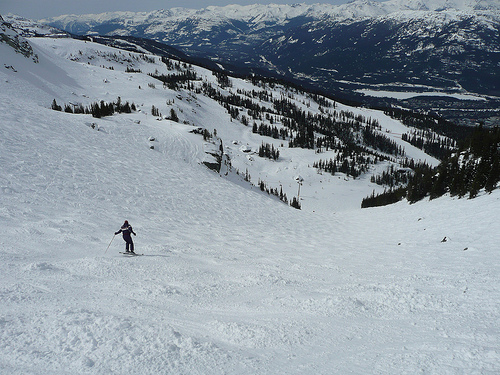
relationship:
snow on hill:
[179, 201, 461, 368] [119, 11, 446, 212]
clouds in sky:
[0, 0, 355, 15] [23, 0, 231, 22]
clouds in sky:
[0, 0, 355, 15] [0, 0, 370, 24]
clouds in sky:
[0, 0, 355, 15] [22, 3, 234, 16]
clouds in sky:
[0, 0, 355, 15] [2, 2, 173, 13]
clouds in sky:
[0, 0, 355, 15] [2, 1, 349, 15]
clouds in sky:
[23, 4, 70, 15] [128, 1, 159, 8]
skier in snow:
[115, 219, 137, 254] [0, 13, 499, 375]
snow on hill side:
[0, 13, 499, 375] [249, 29, 343, 80]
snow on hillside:
[330, 5, 476, 25] [45, 45, 247, 238]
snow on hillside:
[0, 13, 499, 375] [35, 68, 295, 229]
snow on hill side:
[36, 0, 500, 35] [244, 7, 475, 80]